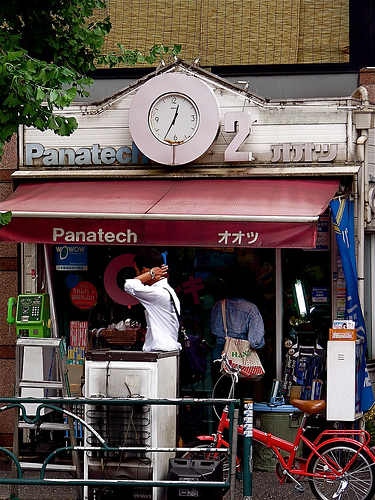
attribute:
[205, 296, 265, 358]
jacket — jean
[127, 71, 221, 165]
clock — white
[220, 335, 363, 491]
bicycle — red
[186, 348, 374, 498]
red bicycle — small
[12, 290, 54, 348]
telephone — green, public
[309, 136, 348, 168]
face — smiley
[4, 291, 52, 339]
telephone — green, lime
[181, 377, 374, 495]
bicycle — red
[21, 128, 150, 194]
sign — pantech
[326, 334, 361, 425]
mail box — white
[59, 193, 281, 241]
tent — red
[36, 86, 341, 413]
front — store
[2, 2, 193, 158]
tree — green, large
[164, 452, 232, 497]
tv — small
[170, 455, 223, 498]
monitor — computer, black, small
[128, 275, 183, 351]
shirt — white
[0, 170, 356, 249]
canopy — maroon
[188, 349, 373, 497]
bike — parked, red, shiny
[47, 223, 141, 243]
word — pantech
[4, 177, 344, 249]
awning — red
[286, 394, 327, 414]
seat — brown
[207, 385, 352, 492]
bike — framed, red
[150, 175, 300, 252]
awning — red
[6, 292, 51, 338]
phone — lime green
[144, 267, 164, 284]
wrist — man's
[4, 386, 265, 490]
railing — metal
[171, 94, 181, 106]
number — black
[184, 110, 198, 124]
number — black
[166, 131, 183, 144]
number — black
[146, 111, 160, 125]
number — black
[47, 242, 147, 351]
window — store's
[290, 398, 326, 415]
seat — brown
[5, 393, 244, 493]
rail — painted, metal, green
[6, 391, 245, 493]
railing — metal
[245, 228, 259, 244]
sign — smilely